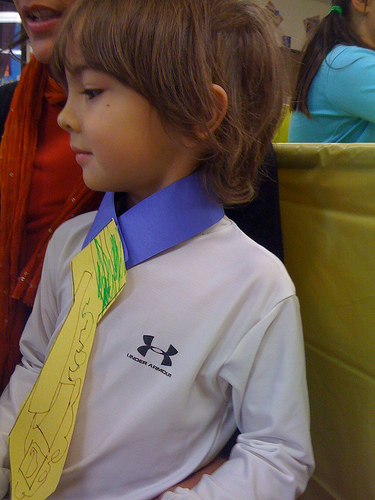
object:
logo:
[136, 331, 180, 371]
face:
[53, 29, 134, 185]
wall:
[267, 145, 374, 499]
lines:
[277, 190, 375, 231]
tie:
[7, 216, 130, 499]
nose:
[56, 92, 81, 130]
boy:
[1, 1, 317, 498]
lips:
[23, 17, 60, 36]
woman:
[0, 0, 117, 395]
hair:
[49, 0, 293, 207]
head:
[57, 1, 281, 200]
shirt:
[0, 171, 315, 499]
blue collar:
[80, 164, 229, 265]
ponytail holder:
[327, 4, 341, 14]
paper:
[6, 218, 127, 500]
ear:
[191, 78, 228, 146]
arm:
[164, 280, 316, 498]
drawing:
[90, 222, 122, 313]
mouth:
[22, 3, 65, 34]